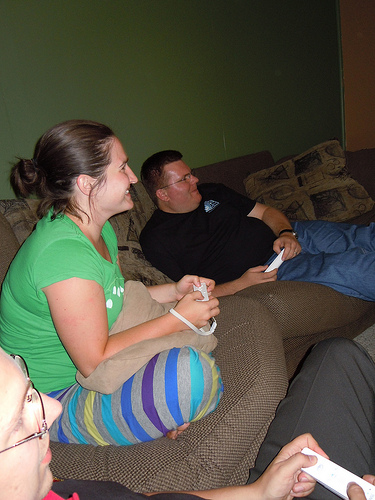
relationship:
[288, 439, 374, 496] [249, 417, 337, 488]
controller in a hand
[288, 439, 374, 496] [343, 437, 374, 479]
controller in a hand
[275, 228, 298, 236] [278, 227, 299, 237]
watch on a watch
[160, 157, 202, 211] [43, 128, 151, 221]
face on person's face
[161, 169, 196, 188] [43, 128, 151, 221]
eyeglasses on person's face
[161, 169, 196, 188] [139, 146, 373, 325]
eyeglasses on man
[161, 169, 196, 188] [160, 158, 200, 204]
eyeglasses on face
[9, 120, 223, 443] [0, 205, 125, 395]
girl wearing a green shirt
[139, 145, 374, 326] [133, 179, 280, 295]
man wearing a black t-shirt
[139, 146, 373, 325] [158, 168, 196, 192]
man wearing glasses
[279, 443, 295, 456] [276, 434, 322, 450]
part of a finger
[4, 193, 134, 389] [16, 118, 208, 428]
green shirt on a woman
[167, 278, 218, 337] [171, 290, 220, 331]
controller in a hand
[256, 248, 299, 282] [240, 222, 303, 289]
controller in a man's hands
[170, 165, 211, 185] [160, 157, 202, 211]
eyeglasses on a face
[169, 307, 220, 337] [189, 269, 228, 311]
controller strap for controller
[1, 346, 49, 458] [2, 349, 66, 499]
glasses on a face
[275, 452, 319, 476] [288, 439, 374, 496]
thumb pressed on controller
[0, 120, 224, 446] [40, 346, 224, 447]
girl smiling in pajama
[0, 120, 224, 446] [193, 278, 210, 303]
girl holding controller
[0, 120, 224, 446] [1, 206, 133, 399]
girl in shirt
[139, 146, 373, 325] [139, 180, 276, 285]
man in black t-shirt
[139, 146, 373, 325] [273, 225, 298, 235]
man with watch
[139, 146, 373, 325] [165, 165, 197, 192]
man wearing glasses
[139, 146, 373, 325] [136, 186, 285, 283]
man wearing shirt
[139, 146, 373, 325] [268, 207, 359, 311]
man wearing jeans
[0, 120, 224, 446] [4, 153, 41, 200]
girl with ponytail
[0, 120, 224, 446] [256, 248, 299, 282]
girl playing controller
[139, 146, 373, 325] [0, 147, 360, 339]
man sitting on couch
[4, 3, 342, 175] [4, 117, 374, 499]
wall behind family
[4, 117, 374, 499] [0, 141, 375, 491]
family on brown sofa